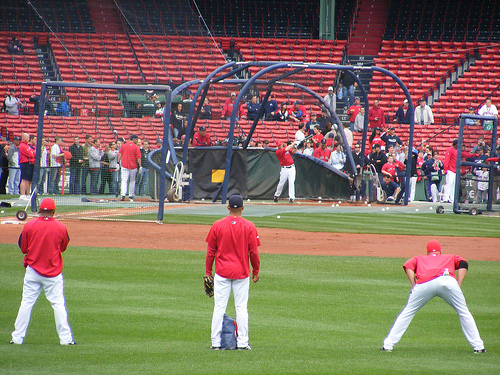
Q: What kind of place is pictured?
A: It is a field.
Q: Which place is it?
A: It is a field.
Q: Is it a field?
A: Yes, it is a field.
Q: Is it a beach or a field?
A: It is a field.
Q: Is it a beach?
A: No, it is a field.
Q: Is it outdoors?
A: Yes, it is outdoors.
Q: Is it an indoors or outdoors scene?
A: It is outdoors.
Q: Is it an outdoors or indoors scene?
A: It is outdoors.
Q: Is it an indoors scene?
A: No, it is outdoors.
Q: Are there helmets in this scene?
A: No, there are no helmets.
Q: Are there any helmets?
A: No, there are no helmets.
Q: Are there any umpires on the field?
A: No, there is a man on the field.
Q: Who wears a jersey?
A: The man wears a jersey.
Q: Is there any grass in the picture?
A: Yes, there is grass.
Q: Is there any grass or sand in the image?
A: Yes, there is grass.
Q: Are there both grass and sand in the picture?
A: No, there is grass but no sand.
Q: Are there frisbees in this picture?
A: No, there are no frisbees.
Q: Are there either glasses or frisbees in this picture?
A: No, there are no frisbees or glasses.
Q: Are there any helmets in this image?
A: No, there are no helmets.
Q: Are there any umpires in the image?
A: No, there are no umpires.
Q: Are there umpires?
A: No, there are no umpires.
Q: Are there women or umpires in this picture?
A: No, there are no umpires or women.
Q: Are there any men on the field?
A: Yes, there is a man on the field.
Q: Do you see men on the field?
A: Yes, there is a man on the field.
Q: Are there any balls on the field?
A: No, there is a man on the field.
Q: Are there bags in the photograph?
A: Yes, there is a bag.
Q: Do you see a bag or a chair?
A: Yes, there is a bag.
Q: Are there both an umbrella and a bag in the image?
A: No, there is a bag but no umbrellas.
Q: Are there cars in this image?
A: No, there are no cars.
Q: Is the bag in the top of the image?
A: No, the bag is in the bottom of the image.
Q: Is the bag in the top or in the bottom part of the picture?
A: The bag is in the bottom of the image.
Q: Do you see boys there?
A: No, there are no boys.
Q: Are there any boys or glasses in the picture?
A: No, there are no boys or glasses.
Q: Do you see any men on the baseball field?
A: Yes, there is a man on the field.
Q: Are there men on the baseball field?
A: Yes, there is a man on the field.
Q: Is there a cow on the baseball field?
A: No, there is a man on the field.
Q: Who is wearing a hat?
A: The man is wearing a hat.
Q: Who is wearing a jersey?
A: The man is wearing a jersey.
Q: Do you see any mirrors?
A: No, there are no mirrors.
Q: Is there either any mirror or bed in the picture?
A: No, there are no mirrors or beds.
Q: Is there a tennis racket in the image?
A: No, there are no rackets.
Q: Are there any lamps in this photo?
A: No, there are no lamps.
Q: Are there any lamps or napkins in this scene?
A: No, there are no lamps or napkins.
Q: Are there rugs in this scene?
A: No, there are no rugs.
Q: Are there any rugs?
A: No, there are no rugs.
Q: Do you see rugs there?
A: No, there are no rugs.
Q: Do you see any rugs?
A: No, there are no rugs.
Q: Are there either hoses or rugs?
A: No, there are no rugs or hoses.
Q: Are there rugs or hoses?
A: No, there are no rugs or hoses.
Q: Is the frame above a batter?
A: Yes, the frame is above a batter.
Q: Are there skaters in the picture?
A: No, there are no skaters.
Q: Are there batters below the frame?
A: Yes, there is a batter below the frame.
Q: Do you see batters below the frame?
A: Yes, there is a batter below the frame.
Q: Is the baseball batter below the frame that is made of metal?
A: Yes, the batter is below the frame.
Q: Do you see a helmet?
A: No, there are no helmets.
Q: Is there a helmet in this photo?
A: No, there are no helmets.